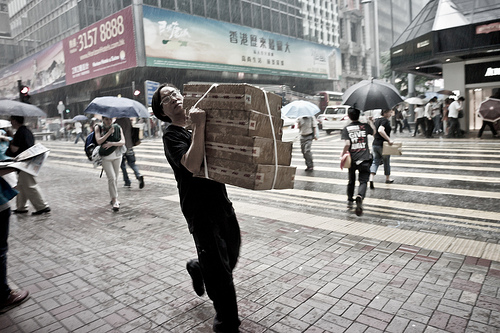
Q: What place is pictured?
A: It is a street.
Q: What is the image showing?
A: It is showing a street.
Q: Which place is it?
A: It is a street.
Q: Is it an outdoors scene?
A: Yes, it is outdoors.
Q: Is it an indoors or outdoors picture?
A: It is outdoors.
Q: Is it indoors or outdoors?
A: It is outdoors.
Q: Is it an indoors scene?
A: No, it is outdoors.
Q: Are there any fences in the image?
A: No, there are no fences.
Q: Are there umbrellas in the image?
A: Yes, there is an umbrella.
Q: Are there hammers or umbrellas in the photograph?
A: Yes, there is an umbrella.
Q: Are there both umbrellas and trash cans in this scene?
A: No, there is an umbrella but no trash cans.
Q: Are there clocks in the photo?
A: No, there are no clocks.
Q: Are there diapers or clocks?
A: No, there are no clocks or diapers.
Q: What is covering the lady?
A: The umbrella is covering the lady.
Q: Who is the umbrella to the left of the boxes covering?
A: The umbrella is covering the lady.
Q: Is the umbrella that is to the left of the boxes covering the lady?
A: Yes, the umbrella is covering the lady.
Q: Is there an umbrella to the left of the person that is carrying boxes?
A: Yes, there is an umbrella to the left of the person.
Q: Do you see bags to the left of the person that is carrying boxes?
A: No, there is an umbrella to the left of the person.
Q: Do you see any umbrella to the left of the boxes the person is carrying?
A: Yes, there is an umbrella to the left of the boxes.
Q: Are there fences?
A: No, there are no fences.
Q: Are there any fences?
A: No, there are no fences.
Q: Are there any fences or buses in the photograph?
A: No, there are no fences or buses.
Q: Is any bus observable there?
A: No, there are no buses.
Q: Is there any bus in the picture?
A: No, there are no buses.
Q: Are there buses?
A: No, there are no buses.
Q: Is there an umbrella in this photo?
A: Yes, there is an umbrella.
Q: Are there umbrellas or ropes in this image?
A: Yes, there is an umbrella.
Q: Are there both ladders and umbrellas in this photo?
A: No, there is an umbrella but no ladders.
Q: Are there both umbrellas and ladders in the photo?
A: No, there is an umbrella but no ladders.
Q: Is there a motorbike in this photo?
A: No, there are no motorcycles.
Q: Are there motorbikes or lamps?
A: No, there are no motorbikes or lamps.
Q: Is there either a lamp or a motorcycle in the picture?
A: No, there are no motorcycles or lamps.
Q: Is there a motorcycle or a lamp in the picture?
A: No, there are no motorcycles or lamps.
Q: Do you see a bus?
A: No, there are no buses.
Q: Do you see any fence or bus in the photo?
A: No, there are no buses or fences.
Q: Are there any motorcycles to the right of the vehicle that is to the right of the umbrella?
A: No, there is a person to the right of the car.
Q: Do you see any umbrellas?
A: Yes, there is an umbrella.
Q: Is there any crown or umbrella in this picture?
A: Yes, there is an umbrella.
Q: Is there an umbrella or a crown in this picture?
A: Yes, there is an umbrella.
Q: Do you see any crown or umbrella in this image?
A: Yes, there is an umbrella.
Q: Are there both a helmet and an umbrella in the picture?
A: No, there is an umbrella but no helmets.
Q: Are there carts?
A: No, there are no carts.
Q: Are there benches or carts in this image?
A: No, there are no carts or benches.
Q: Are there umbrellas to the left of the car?
A: Yes, there is an umbrella to the left of the car.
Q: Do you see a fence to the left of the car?
A: No, there is an umbrella to the left of the car.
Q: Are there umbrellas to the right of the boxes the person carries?
A: Yes, there is an umbrella to the right of the boxes.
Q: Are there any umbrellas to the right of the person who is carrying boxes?
A: Yes, there is an umbrella to the right of the person.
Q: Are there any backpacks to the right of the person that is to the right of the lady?
A: No, there is an umbrella to the right of the person.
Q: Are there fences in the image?
A: No, there are no fences.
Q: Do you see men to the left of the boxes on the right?
A: Yes, there is a man to the left of the boxes.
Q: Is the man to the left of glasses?
A: No, the man is to the left of the boxes.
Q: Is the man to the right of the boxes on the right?
A: No, the man is to the left of the boxes.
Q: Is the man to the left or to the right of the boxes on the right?
A: The man is to the left of the boxes.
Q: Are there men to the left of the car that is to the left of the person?
A: Yes, there is a man to the left of the car.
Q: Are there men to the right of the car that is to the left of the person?
A: No, the man is to the left of the car.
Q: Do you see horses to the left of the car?
A: No, there is a man to the left of the car.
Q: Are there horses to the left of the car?
A: No, there is a man to the left of the car.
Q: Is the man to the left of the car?
A: Yes, the man is to the left of the car.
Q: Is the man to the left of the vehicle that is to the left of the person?
A: Yes, the man is to the left of the car.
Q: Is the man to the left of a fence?
A: No, the man is to the left of the car.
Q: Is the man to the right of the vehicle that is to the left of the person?
A: No, the man is to the left of the car.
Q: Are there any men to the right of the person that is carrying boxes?
A: Yes, there is a man to the right of the person.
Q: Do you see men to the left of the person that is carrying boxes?
A: No, the man is to the right of the person.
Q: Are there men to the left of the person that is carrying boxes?
A: No, the man is to the right of the person.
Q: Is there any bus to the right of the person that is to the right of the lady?
A: No, there is a man to the right of the person.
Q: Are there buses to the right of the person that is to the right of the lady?
A: No, there is a man to the right of the person.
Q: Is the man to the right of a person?
A: Yes, the man is to the right of a person.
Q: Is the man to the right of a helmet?
A: No, the man is to the right of a person.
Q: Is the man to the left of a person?
A: No, the man is to the right of a person.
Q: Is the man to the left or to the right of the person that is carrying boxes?
A: The man is to the right of the person.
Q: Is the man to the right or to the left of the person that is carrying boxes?
A: The man is to the right of the person.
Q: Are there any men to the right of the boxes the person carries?
A: Yes, there is a man to the right of the boxes.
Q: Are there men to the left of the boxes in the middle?
A: No, the man is to the right of the boxes.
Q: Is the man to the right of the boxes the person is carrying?
A: Yes, the man is to the right of the boxes.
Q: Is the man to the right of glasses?
A: No, the man is to the right of the boxes.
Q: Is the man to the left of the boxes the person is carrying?
A: No, the man is to the right of the boxes.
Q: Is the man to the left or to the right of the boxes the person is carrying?
A: The man is to the right of the boxes.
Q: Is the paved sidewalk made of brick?
A: Yes, the side walk is made of brick.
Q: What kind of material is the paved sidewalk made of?
A: The side walk is made of brick.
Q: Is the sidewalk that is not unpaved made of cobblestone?
A: No, the sidewalk is made of brick.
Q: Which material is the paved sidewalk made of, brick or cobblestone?
A: The sidewalk is made of brick.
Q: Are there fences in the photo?
A: No, there are no fences.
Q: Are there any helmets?
A: No, there are no helmets.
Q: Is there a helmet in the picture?
A: No, there are no helmets.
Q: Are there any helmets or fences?
A: No, there are no helmets or fences.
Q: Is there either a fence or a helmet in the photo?
A: No, there are no helmets or fences.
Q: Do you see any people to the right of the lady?
A: Yes, there is a person to the right of the lady.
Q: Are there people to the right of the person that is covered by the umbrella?
A: Yes, there is a person to the right of the lady.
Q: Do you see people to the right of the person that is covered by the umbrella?
A: Yes, there is a person to the right of the lady.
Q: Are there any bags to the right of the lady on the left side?
A: No, there is a person to the right of the lady.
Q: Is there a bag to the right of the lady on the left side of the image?
A: No, there is a person to the right of the lady.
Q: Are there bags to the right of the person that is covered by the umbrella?
A: No, there is a person to the right of the lady.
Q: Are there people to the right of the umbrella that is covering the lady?
A: Yes, there is a person to the right of the umbrella.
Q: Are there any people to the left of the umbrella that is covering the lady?
A: No, the person is to the right of the umbrella.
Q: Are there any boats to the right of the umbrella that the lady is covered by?
A: No, there is a person to the right of the umbrella.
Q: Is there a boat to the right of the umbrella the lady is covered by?
A: No, there is a person to the right of the umbrella.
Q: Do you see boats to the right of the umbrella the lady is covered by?
A: No, there is a person to the right of the umbrella.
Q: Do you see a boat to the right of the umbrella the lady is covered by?
A: No, there is a person to the right of the umbrella.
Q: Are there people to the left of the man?
A: Yes, there is a person to the left of the man.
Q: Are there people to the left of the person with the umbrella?
A: Yes, there is a person to the left of the man.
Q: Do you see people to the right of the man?
A: No, the person is to the left of the man.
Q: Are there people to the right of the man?
A: No, the person is to the left of the man.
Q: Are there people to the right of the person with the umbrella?
A: No, the person is to the left of the man.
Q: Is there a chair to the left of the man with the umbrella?
A: No, there is a person to the left of the man.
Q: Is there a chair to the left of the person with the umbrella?
A: No, there is a person to the left of the man.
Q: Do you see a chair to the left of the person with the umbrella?
A: No, there is a person to the left of the man.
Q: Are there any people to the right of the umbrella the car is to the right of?
A: No, the person is to the left of the umbrella.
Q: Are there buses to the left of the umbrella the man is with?
A: No, there is a person to the left of the umbrella.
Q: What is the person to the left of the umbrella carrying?
A: The person is carrying boxes.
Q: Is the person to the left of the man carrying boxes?
A: Yes, the person is carrying boxes.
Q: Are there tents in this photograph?
A: No, there are no tents.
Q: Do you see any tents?
A: No, there are no tents.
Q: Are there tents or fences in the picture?
A: No, there are no tents or fences.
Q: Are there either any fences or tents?
A: No, there are no tents or fences.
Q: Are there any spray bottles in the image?
A: No, there are no spray bottles.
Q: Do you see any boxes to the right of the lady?
A: Yes, there are boxes to the right of the lady.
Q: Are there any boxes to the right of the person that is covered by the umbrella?
A: Yes, there are boxes to the right of the lady.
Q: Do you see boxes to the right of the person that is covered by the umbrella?
A: Yes, there are boxes to the right of the lady.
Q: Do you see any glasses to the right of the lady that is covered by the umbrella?
A: No, there are boxes to the right of the lady.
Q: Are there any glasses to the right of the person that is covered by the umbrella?
A: No, there are boxes to the right of the lady.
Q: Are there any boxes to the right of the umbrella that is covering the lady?
A: Yes, there are boxes to the right of the umbrella.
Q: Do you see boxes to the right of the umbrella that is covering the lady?
A: Yes, there are boxes to the right of the umbrella.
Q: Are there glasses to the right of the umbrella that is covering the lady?
A: No, there are boxes to the right of the umbrella.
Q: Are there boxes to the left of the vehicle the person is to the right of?
A: Yes, there are boxes to the left of the car.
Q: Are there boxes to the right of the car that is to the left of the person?
A: No, the boxes are to the left of the car.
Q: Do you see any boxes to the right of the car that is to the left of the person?
A: No, the boxes are to the left of the car.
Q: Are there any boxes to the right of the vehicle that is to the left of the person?
A: No, the boxes are to the left of the car.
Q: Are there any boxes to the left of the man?
A: Yes, there are boxes to the left of the man.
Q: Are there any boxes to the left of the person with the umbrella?
A: Yes, there are boxes to the left of the man.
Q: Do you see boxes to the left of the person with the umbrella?
A: Yes, there are boxes to the left of the man.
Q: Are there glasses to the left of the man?
A: No, there are boxes to the left of the man.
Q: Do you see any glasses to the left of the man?
A: No, there are boxes to the left of the man.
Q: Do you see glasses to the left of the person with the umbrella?
A: No, there are boxes to the left of the man.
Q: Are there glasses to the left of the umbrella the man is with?
A: No, there are boxes to the left of the umbrella.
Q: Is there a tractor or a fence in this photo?
A: No, there are no fences or tractors.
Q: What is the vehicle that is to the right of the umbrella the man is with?
A: The vehicle is a car.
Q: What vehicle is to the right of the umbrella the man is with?
A: The vehicle is a car.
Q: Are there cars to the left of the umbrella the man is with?
A: No, the car is to the right of the umbrella.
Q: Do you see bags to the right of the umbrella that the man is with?
A: No, there is a car to the right of the umbrella.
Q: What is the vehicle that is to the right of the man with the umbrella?
A: The vehicle is a car.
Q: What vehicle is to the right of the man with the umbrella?
A: The vehicle is a car.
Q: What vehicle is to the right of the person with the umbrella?
A: The vehicle is a car.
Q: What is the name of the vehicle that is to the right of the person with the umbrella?
A: The vehicle is a car.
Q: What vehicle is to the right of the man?
A: The vehicle is a car.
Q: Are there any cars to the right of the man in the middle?
A: Yes, there is a car to the right of the man.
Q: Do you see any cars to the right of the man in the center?
A: Yes, there is a car to the right of the man.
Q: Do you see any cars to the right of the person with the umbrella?
A: Yes, there is a car to the right of the man.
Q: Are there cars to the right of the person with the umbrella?
A: Yes, there is a car to the right of the man.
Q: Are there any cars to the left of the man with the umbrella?
A: No, the car is to the right of the man.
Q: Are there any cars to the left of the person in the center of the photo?
A: No, the car is to the right of the man.